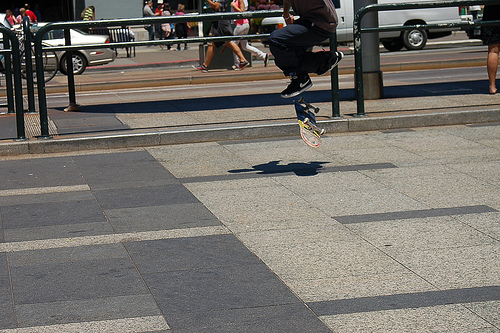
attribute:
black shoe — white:
[281, 72, 313, 99]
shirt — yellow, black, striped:
[82, 5, 94, 21]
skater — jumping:
[272, 2, 352, 102]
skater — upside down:
[292, 82, 347, 152]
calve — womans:
[486, 49, 498, 76]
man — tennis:
[262, 4, 360, 157]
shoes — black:
[268, 65, 328, 108]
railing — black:
[30, 9, 498, 136]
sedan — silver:
[3, 19, 120, 79]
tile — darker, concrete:
[94, 175, 200, 212]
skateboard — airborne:
[291, 98, 326, 151]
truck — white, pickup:
[261, 5, 468, 47]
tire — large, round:
[9, 35, 64, 84]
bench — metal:
[91, 20, 138, 57]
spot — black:
[382, 240, 392, 249]